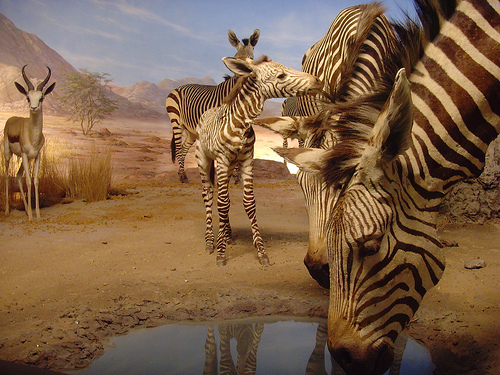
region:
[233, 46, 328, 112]
face of zebra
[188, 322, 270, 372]
shadow falling in water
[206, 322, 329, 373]
zebra shadow in water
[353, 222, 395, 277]
eye of the zebra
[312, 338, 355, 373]
nose of the zebra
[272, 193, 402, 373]
zebra drinking the water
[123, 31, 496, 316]
group of zebra standing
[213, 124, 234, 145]
skin of the zebra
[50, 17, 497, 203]
a beautiful view of sky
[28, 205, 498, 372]
a clean sand around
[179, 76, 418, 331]
the zebras are visible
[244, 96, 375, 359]
the zebras are visible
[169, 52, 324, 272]
Baby zebra near the water.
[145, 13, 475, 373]
Animals around water puddle.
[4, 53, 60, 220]
Antelope facing the camera.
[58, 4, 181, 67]
Clouds in the sky.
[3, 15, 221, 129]
Small mountain range in the background.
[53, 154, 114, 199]
Dry grass next to the antelope.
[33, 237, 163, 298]
The ground is brown.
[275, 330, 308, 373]
Sky reflection in the water.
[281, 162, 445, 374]
Zebra head over the water.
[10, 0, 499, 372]
Display at a museum.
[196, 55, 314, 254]
a young brown and beige stripped zebra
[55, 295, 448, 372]
a shallow pond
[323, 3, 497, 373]
a large beige and dark brown zebra drinking from a pond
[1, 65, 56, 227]
a thin antelope.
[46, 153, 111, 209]
a dry patch of tall grass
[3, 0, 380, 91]
a blue slightly cloudy sky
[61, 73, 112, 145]
a tree on the desert plains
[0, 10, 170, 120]
a distant mountain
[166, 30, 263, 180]
a zebra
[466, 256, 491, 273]
a rock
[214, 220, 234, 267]
tall leg of zebra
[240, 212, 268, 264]
tall leg of zebra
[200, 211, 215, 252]
tall leg of zebra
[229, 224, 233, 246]
tall leg of zebra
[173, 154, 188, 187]
tall leg of zebra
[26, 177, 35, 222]
tall leg of gazelle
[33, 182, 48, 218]
tall leg of gazelle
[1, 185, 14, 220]
tall leg of gazelle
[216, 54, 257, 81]
ear of small zebra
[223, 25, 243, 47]
ear of small zebra